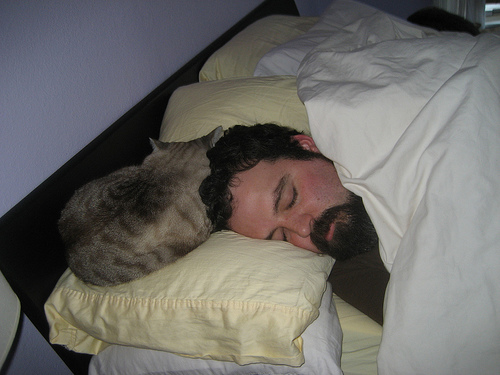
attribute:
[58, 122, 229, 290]
cat — sleeping, pictured, grey, fat, white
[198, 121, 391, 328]
man — pictured, sleeping, light skinned, beardy, bearded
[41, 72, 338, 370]
pillow — yellow, tan, pictured, cream colored, white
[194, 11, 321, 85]
pillow — yellow, unoccupied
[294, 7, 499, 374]
sheet — one, cream colored, white, yellow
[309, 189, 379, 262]
beard — brown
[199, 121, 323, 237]
hair — brown, black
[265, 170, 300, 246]
eyes — closed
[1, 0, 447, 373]
wall — white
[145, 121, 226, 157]
ears — pointy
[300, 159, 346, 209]
cheek — shaved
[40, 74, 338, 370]
pillowcase — yellow, white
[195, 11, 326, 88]
pillowcase — yellow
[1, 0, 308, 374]
headboard — black